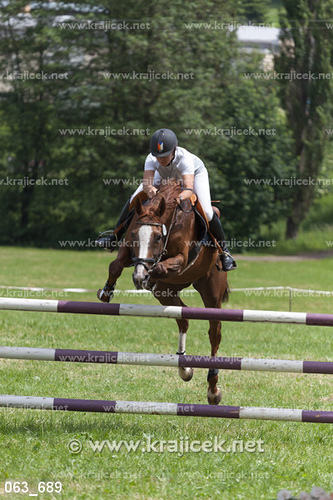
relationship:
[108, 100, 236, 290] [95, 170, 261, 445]
woman riding horse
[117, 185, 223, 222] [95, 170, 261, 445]
saddle on horse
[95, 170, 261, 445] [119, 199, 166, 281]
horse has white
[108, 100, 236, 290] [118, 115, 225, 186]
woman wears helmet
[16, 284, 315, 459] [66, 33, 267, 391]
poles in front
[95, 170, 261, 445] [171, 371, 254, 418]
horse has hooves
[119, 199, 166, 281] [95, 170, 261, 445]
white on horse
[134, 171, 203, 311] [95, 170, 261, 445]
reigns on horse